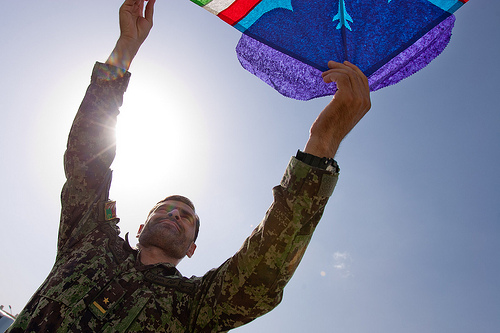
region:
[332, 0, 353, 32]
a light blue plane design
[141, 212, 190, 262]
scruff on a man's face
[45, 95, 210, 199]
white light from the sun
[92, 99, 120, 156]
white beams from the sun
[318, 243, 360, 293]
thin wisps of white cloud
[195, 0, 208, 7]
a green portion of a kite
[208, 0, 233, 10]
a white stripe on a kite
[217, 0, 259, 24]
a red stripe on a kite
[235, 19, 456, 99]
blue kite material in the front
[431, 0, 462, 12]
a light blue stripe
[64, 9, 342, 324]
a military man in uniform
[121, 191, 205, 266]
the head of an adult man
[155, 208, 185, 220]
the nose of an adult man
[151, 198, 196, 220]
the eyes of an adult man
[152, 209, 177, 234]
the mouth of an adult man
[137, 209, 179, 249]
the chin of an adult man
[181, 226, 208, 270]
the ear of an adult man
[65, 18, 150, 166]
the arm of an adult man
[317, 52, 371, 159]
the hand of an adult man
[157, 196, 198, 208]
the hair of an adult man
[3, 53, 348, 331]
green army uniform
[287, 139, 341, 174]
black wristband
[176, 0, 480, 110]
multi-colored material in person's hand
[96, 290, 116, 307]
yellow star on front of uniform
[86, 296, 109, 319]
yellow stripe on front of uniform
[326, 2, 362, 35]
blue plane shaped image on piece of fabric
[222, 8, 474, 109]
purple edges of material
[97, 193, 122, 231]
badge on shoulder of uniform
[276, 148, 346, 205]
cuff of uniform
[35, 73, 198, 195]
round sun shining in sky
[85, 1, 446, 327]
a soldier holding a kite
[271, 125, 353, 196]
the watch is black